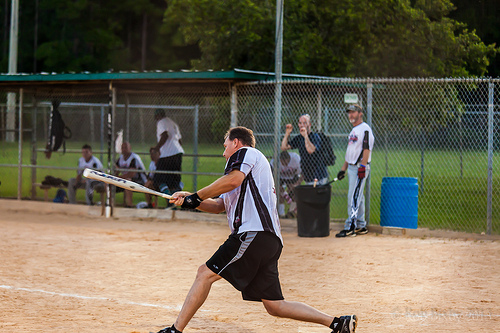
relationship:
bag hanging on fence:
[48, 101, 67, 153] [2, 84, 498, 244]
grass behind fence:
[2, 138, 499, 236] [2, 84, 498, 244]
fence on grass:
[395, 74, 499, 221] [431, 161, 476, 208]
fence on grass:
[395, 74, 499, 221] [398, 147, 466, 170]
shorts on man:
[206, 227, 284, 303] [142, 125, 359, 331]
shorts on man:
[150, 153, 184, 186] [147, 108, 182, 210]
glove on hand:
[148, 145, 160, 161] [151, 145, 160, 156]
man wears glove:
[144, 104, 184, 214] [148, 145, 160, 161]